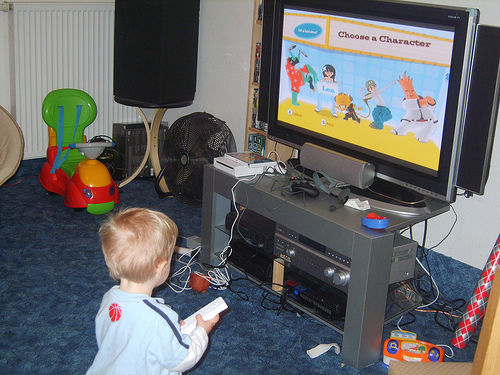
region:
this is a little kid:
[98, 207, 245, 335]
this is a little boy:
[81, 166, 258, 326]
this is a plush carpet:
[261, 320, 281, 370]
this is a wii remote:
[183, 294, 247, 349]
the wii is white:
[173, 281, 214, 345]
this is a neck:
[56, 238, 193, 308]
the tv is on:
[267, 61, 494, 156]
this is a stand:
[241, 182, 336, 253]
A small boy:
[89, 199, 224, 373]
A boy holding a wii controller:
[76, 203, 233, 373]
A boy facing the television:
[62, 162, 239, 373]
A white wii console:
[208, 141, 260, 183]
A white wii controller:
[175, 292, 230, 335]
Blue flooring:
[1, 155, 496, 372]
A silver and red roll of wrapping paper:
[445, 235, 498, 351]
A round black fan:
[141, 112, 243, 217]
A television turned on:
[258, 0, 483, 210]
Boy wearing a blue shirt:
[82, 199, 228, 372]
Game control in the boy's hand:
[175, 296, 230, 336]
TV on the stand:
[254, 0, 498, 224]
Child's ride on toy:
[29, 75, 121, 221]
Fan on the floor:
[151, 111, 237, 211]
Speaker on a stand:
[107, 0, 208, 197]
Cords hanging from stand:
[169, 180, 244, 299]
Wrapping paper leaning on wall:
[452, 231, 498, 348]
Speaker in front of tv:
[289, 133, 381, 193]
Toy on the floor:
[382, 321, 447, 373]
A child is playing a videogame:
[26, 5, 493, 371]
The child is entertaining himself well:
[31, 42, 496, 357]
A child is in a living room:
[50, 20, 475, 366]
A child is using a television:
[25, 35, 496, 361]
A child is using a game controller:
[27, 50, 467, 371]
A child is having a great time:
[8, 20, 496, 365]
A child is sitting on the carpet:
[25, 62, 486, 372]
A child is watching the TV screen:
[0, 5, 470, 363]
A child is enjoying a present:
[11, 37, 492, 357]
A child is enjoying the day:
[35, 34, 482, 364]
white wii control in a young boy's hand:
[175, 293, 230, 333]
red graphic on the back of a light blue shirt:
[105, 300, 122, 320]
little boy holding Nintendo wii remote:
[83, 205, 229, 373]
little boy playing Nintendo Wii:
[82, 201, 230, 373]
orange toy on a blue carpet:
[383, 327, 444, 363]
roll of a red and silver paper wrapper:
[449, 234, 499, 350]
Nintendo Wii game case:
[221, 148, 274, 164]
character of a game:
[388, 70, 440, 150]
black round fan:
[158, 109, 236, 208]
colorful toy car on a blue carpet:
[36, 87, 122, 217]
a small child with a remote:
[84, 205, 228, 373]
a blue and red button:
[362, 209, 388, 231]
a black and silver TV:
[258, 1, 481, 207]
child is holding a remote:
[87, 209, 224, 374]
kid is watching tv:
[73, 207, 227, 374]